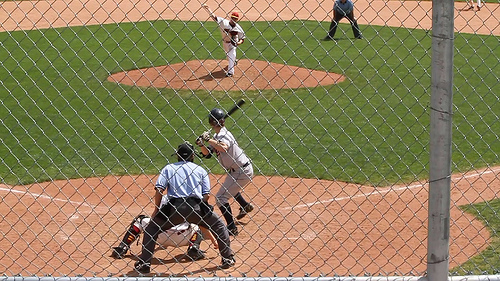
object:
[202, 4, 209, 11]
ball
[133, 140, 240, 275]
umpire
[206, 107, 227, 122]
helmet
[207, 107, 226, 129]
head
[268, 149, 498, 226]
line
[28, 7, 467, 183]
baseball field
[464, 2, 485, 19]
fielder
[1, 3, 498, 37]
dirt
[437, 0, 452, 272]
pole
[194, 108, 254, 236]
baseball player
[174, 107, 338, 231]
player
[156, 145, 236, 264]
umpire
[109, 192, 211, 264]
catcher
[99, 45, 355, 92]
mound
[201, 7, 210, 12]
right hand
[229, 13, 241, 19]
hat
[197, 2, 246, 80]
pitcher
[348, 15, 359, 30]
hand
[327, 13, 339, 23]
hand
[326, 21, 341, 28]
knee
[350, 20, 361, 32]
knee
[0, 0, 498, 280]
metal fence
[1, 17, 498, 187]
grass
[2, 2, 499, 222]
infield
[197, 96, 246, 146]
baseballbat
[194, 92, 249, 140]
bat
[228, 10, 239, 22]
cap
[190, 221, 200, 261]
leg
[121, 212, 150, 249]
leg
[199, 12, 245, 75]
player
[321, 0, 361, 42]
player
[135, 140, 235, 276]
player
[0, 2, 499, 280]
fence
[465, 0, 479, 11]
man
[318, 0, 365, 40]
man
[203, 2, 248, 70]
man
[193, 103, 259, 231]
man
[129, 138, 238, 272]
man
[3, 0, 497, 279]
field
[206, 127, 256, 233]
uniform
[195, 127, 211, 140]
hand